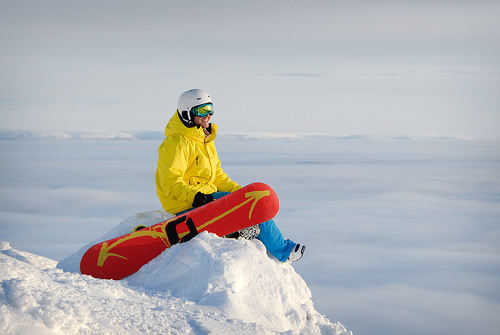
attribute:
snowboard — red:
[80, 180, 281, 280]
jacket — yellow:
[153, 115, 239, 212]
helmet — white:
[176, 87, 215, 122]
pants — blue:
[211, 186, 298, 264]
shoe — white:
[281, 240, 305, 267]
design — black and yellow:
[89, 185, 275, 266]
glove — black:
[190, 186, 213, 210]